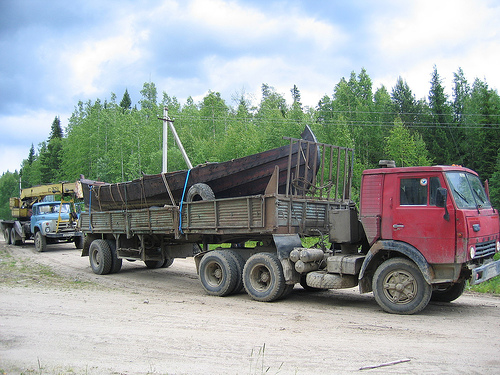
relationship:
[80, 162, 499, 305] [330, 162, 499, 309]
truck has cab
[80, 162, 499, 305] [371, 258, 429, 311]
truck has wheel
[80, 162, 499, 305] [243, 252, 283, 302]
truck has wheel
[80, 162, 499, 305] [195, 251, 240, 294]
truck has wheel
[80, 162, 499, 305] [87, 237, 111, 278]
truck has wheel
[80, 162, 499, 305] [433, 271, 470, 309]
truck has wheel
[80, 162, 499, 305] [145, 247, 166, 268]
truck has wheel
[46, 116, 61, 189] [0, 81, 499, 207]
tree in forest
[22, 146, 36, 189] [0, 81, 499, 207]
tree in forest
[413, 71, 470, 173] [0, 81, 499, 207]
tree in forest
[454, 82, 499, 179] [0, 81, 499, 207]
tree in forest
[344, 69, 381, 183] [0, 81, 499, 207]
tree in forest